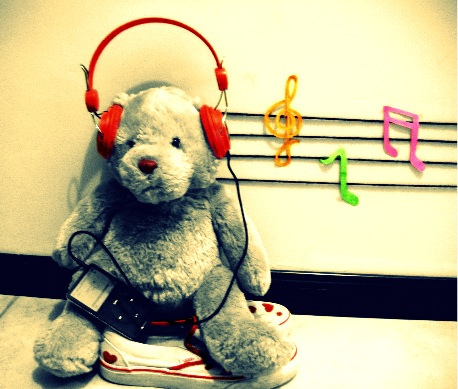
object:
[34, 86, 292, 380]
teddy bear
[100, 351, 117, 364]
shoe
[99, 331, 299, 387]
shoe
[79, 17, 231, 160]
headphones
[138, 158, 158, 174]
nose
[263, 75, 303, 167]
music symbol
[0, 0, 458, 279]
wall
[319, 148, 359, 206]
music note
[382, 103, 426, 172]
music note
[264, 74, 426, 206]
music symbol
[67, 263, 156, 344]
ipod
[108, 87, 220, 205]
head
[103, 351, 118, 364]
heart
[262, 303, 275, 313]
heart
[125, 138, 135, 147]
eye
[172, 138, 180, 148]
eye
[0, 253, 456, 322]
border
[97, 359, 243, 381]
stripe